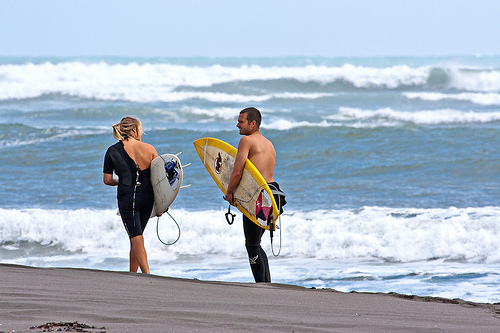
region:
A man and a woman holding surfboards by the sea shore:
[100, 102, 292, 292]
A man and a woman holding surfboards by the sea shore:
[93, 101, 292, 301]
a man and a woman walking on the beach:
[103, 105, 284, 282]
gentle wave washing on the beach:
[3, 207, 498, 305]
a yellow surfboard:
[191, 139, 278, 229]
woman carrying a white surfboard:
[147, 150, 191, 215]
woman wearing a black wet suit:
[103, 143, 155, 236]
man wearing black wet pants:
[242, 215, 269, 286]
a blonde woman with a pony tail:
[111, 116, 143, 141]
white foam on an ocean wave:
[0, 63, 499, 130]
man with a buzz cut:
[236, 107, 261, 136]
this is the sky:
[208, 8, 308, 54]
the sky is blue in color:
[256, 17, 326, 59]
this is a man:
[230, 90, 290, 275]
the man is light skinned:
[247, 130, 269, 149]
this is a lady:
[92, 114, 155, 233]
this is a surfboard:
[148, 139, 187, 218]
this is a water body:
[356, 114, 462, 234]